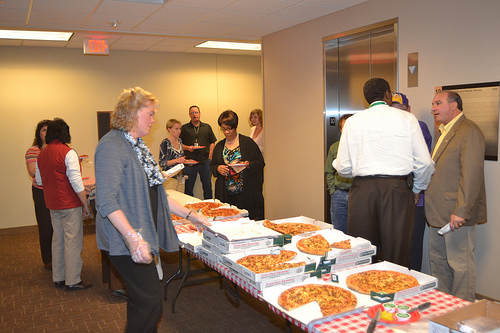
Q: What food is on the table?
A: Pizza.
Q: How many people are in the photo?
A: Eleven.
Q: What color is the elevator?
A: Silver.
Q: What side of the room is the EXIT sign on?
A: Left.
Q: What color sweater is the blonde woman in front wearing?
A: Grey.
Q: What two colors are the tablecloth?
A: Red, white.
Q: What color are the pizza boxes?
A: White.